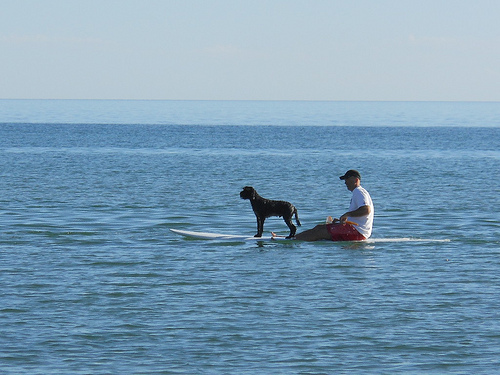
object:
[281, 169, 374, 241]
man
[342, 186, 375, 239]
shirt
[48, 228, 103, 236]
ripple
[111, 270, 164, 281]
ripple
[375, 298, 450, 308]
ripple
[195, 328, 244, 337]
ripple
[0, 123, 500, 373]
water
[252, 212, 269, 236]
leg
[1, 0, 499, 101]
sky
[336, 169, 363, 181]
hat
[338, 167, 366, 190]
head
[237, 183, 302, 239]
dog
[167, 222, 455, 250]
surfboard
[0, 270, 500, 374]
calm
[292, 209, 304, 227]
tail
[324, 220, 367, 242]
pair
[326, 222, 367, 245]
shorts